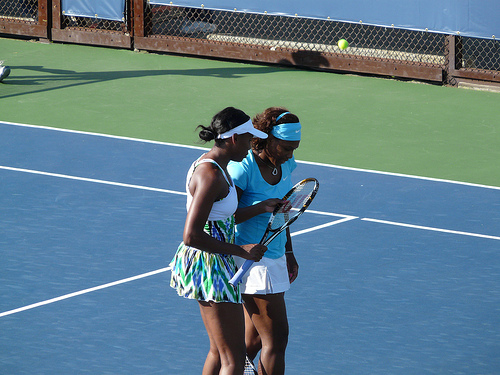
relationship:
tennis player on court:
[169, 107, 253, 373] [1, 39, 499, 374]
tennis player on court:
[227, 107, 300, 374] [1, 39, 499, 374]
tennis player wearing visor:
[169, 107, 253, 373] [217, 117, 268, 139]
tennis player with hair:
[169, 107, 253, 373] [197, 106, 251, 146]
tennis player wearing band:
[227, 107, 300, 374] [273, 123, 301, 140]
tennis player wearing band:
[227, 107, 300, 374] [275, 110, 293, 120]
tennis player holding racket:
[169, 107, 253, 373] [227, 176, 319, 285]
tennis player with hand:
[169, 107, 253, 373] [241, 243, 268, 262]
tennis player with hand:
[169, 107, 253, 373] [264, 198, 291, 214]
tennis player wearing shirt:
[227, 107, 300, 374] [225, 150, 297, 259]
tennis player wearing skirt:
[227, 107, 300, 374] [230, 252, 290, 296]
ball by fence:
[338, 39, 349, 50] [0, 1, 499, 85]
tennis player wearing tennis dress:
[169, 107, 253, 373] [169, 151, 245, 302]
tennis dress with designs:
[169, 151, 245, 302] [169, 215, 241, 304]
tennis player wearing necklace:
[227, 107, 300, 374] [254, 152, 282, 176]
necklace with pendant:
[254, 152, 282, 176] [272, 167, 279, 175]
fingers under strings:
[279, 198, 292, 213] [272, 180, 316, 228]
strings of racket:
[272, 180, 316, 228] [227, 176, 319, 285]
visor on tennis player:
[217, 117, 268, 139] [169, 107, 253, 373]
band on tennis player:
[273, 123, 301, 140] [227, 107, 300, 374]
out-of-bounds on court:
[0, 37, 499, 185] [1, 39, 499, 374]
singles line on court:
[0, 217, 357, 319] [1, 39, 499, 374]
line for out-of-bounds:
[0, 120, 499, 191] [0, 37, 499, 185]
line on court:
[0, 120, 499, 191] [1, 39, 499, 374]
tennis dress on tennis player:
[169, 151, 245, 302] [169, 107, 253, 373]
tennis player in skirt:
[169, 107, 253, 373] [230, 252, 290, 296]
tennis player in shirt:
[169, 107, 253, 373] [225, 150, 297, 259]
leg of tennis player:
[198, 301, 221, 374] [169, 107, 253, 373]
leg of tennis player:
[203, 301, 245, 374] [169, 107, 253, 373]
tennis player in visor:
[169, 107, 253, 373] [217, 117, 268, 139]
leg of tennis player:
[242, 304, 263, 361] [227, 107, 300, 374]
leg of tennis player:
[242, 292, 290, 374] [227, 107, 300, 374]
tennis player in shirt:
[227, 107, 300, 374] [225, 150, 297, 259]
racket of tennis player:
[227, 176, 319, 285] [169, 107, 253, 373]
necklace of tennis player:
[254, 152, 282, 176] [227, 107, 300, 374]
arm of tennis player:
[184, 170, 242, 255] [169, 107, 253, 373]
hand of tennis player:
[286, 257, 299, 282] [227, 107, 300, 374]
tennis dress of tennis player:
[169, 151, 245, 302] [169, 107, 253, 373]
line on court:
[1, 164, 499, 240] [1, 39, 499, 374]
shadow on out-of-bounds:
[2, 36, 331, 99] [0, 37, 499, 185]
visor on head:
[217, 117, 268, 139] [211, 107, 253, 161]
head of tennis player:
[211, 107, 253, 161] [169, 107, 253, 373]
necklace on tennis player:
[254, 152, 282, 176] [227, 107, 300, 374]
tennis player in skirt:
[227, 107, 300, 374] [230, 252, 290, 296]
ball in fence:
[338, 39, 349, 50] [0, 1, 499, 85]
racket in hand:
[227, 176, 319, 285] [241, 243, 268, 262]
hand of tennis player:
[241, 243, 268, 262] [169, 107, 253, 373]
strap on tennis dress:
[195, 159, 231, 187] [169, 151, 245, 302]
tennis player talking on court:
[169, 107, 253, 373] [1, 39, 499, 374]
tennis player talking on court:
[227, 107, 300, 374] [1, 39, 499, 374]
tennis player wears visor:
[169, 107, 253, 373] [217, 117, 268, 139]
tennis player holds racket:
[169, 107, 253, 373] [227, 176, 319, 285]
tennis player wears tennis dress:
[169, 107, 253, 373] [169, 151, 245, 302]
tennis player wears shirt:
[227, 107, 300, 374] [225, 150, 297, 259]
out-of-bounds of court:
[0, 37, 499, 185] [1, 39, 499, 374]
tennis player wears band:
[227, 107, 300, 374] [273, 123, 301, 140]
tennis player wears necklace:
[227, 107, 300, 374] [254, 152, 282, 176]